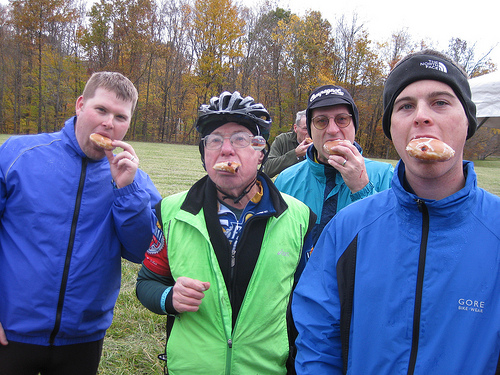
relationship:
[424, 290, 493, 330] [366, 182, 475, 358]
logo on jacket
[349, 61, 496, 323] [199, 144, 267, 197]
man with doughnut